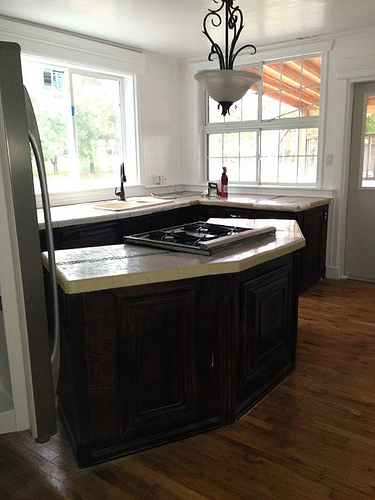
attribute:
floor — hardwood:
[94, 467, 362, 491]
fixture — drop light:
[198, 1, 255, 120]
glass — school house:
[191, 66, 263, 106]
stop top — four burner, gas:
[123, 222, 278, 256]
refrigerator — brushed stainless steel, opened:
[0, 39, 59, 444]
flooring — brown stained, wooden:
[0, 277, 374, 498]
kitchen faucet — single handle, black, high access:
[113, 162, 126, 201]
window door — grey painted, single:
[344, 82, 373, 279]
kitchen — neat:
[0, 0, 374, 497]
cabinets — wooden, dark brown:
[48, 257, 299, 468]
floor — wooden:
[0, 277, 373, 498]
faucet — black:
[113, 161, 127, 201]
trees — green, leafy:
[25, 72, 125, 173]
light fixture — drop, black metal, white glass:
[191, 0, 262, 115]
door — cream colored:
[343, 79, 363, 278]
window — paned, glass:
[21, 60, 130, 195]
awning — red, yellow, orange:
[239, 56, 322, 115]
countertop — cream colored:
[37, 189, 330, 230]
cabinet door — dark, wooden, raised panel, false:
[118, 284, 197, 437]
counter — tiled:
[41, 215, 308, 295]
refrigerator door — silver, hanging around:
[1, 40, 63, 443]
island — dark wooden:
[38, 214, 307, 470]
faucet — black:
[116, 162, 133, 204]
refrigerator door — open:
[0, 36, 68, 483]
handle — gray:
[21, 120, 66, 370]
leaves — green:
[80, 116, 92, 135]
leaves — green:
[50, 113, 62, 127]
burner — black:
[160, 214, 247, 265]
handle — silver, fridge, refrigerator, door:
[24, 83, 60, 390]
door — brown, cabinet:
[117, 288, 200, 430]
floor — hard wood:
[19, 280, 363, 495]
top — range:
[122, 218, 278, 254]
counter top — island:
[40, 218, 307, 295]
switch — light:
[323, 152, 333, 169]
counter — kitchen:
[29, 189, 329, 233]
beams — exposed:
[245, 57, 332, 114]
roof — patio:
[244, 60, 321, 108]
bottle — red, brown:
[217, 166, 229, 198]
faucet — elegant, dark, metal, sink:
[112, 161, 128, 204]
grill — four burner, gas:
[121, 215, 277, 257]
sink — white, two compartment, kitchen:
[92, 187, 176, 215]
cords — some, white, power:
[150, 177, 184, 201]